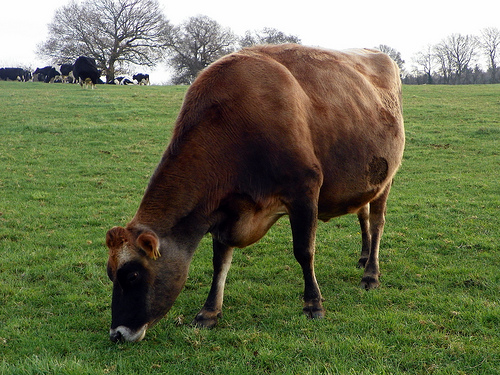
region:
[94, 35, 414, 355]
brown cow grazing in grass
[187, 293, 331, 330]
two cow hooves in grass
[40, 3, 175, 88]
tall large leafless tree in field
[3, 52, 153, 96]
group of black and white cows in field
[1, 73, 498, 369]
large green field of grass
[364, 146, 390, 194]
bald spot on cow fur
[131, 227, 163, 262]
brown cow ear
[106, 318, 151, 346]
white and black cow snout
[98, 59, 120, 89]
brown tree trunk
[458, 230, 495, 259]
black spot on green grass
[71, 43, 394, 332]
brown cow eating grass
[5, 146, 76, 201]
short brown and green grass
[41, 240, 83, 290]
short brown and green grass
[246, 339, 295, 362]
short brown and green grass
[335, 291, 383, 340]
short brown and green grass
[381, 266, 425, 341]
short brown and green grass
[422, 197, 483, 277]
short brown and green grass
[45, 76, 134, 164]
short brown and green grass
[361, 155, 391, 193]
Cow missing a patch of fur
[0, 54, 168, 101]
Group of cows in the distance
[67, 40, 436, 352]
Ernomus brown and Black cow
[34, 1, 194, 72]
Tree without any leafs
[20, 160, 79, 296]
Green Pastors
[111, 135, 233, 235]
Long streched out neck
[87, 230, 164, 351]
Cow eatting grass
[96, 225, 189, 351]
multicolored face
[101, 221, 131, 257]
Bump on top of the cow head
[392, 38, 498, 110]
Far back tree line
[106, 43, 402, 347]
a brown cow grazing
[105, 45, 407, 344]
cow has dark brown, brown, and white face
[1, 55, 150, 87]
herd of cows in the background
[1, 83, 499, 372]
green pasture field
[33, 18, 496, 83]
bare trees with no leaves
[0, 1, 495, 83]
white colored sky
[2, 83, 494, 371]
some brown grass mixed with the green grass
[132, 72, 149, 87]
black and white cow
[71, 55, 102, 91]
black cow with white feet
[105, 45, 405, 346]
cow's eyes are open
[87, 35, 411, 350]
cow nearest to the camera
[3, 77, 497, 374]
green grassy field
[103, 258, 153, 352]
cow's black face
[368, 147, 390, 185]
sore on cow's left side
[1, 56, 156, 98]
group of cows near trees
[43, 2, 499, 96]
group of bare trees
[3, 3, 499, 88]
bright white sky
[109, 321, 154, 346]
white nose of a grazing cow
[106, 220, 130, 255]
bump on a cow's head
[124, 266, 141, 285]
left eye of nearest cow